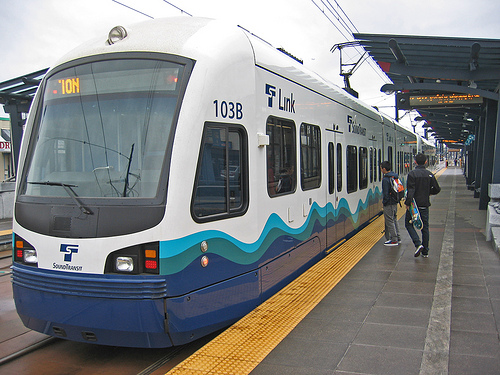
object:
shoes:
[385, 239, 403, 243]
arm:
[404, 175, 416, 205]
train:
[9, 16, 439, 348]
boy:
[380, 161, 402, 246]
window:
[189, 121, 248, 225]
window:
[265, 115, 297, 198]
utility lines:
[110, 0, 437, 143]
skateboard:
[398, 173, 424, 231]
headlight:
[116, 256, 134, 272]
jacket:
[382, 171, 399, 206]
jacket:
[403, 166, 441, 207]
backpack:
[388, 176, 403, 203]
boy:
[403, 153, 441, 257]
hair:
[415, 153, 426, 165]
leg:
[382, 204, 401, 242]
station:
[0, 0, 499, 375]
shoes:
[383, 239, 399, 246]